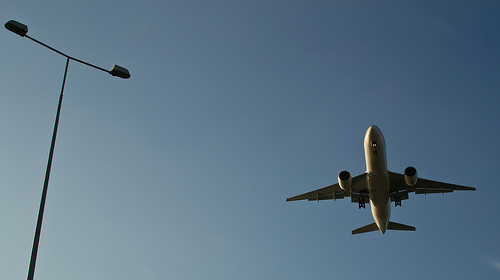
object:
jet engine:
[337, 170, 352, 190]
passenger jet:
[286, 125, 478, 235]